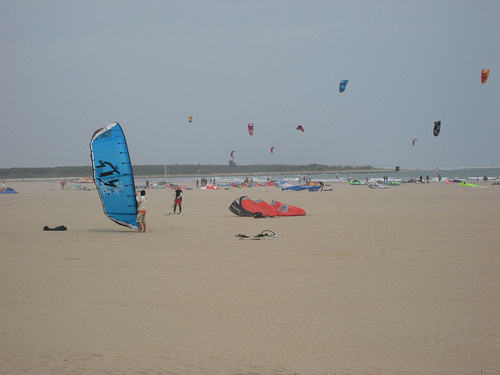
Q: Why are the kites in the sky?
A: People are flying them.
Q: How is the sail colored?
A: Blue.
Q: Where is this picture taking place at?
A: The beach.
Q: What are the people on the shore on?
A: Sand.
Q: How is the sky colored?
A: Blue.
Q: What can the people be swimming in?
A: The ocean.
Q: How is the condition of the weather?
A: Overcast.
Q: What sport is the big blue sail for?
A: Wind Surfing.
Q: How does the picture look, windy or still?
A: Windy.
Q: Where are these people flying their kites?
A: Beach.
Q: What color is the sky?
A: Blue.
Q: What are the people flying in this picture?
A: Kites.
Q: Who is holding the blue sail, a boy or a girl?
A: Boy.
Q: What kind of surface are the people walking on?
A: Sandy.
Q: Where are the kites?
A: In the sky.